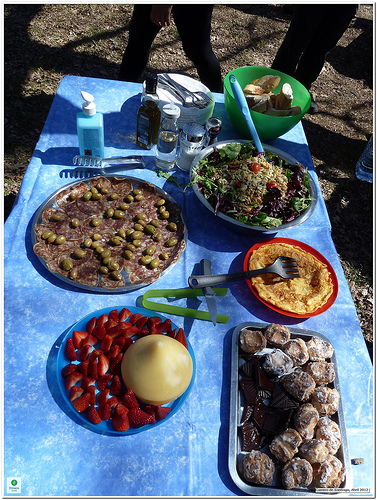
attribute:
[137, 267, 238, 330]
tongs — silver, green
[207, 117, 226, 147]
shaker — pepper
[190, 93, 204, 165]
bottle — large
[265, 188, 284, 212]
olive — green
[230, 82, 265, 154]
knife — sharp, large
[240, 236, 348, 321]
platei — blue, red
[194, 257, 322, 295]
fork — metal, black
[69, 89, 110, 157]
soap — blue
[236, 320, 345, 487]
tray — silver, green, cookies, red, metal, pizza, dessert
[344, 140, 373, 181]
shoe — person's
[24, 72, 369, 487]
tablecloth — blue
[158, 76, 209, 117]
plates — paper, white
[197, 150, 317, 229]
bowl — green, blue, red, salad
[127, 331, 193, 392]
sauce — mountain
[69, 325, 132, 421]
strawberries — red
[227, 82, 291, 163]
spoon — blue